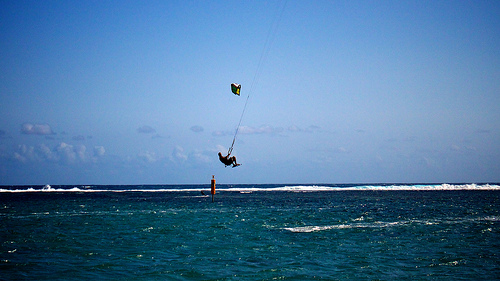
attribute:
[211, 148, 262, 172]
man — flying, riding, holding on, high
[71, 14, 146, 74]
sky — cloudy, blue, clear, sunny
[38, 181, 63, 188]
wave — crashing, far, white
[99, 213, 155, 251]
ocean — blue, calm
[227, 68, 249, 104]
kite — high